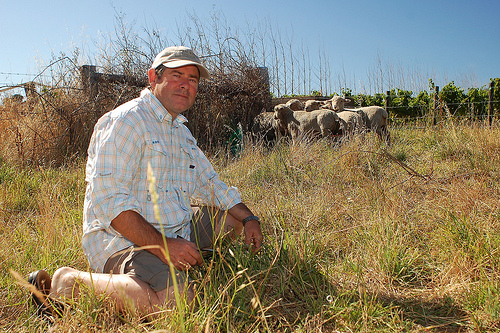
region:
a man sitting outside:
[19, 43, 463, 323]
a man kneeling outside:
[41, 16, 333, 326]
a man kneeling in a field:
[29, 40, 316, 332]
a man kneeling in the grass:
[61, 31, 332, 328]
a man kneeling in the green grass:
[14, 16, 353, 331]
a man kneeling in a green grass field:
[37, 11, 324, 322]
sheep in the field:
[232, 1, 499, 288]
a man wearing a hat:
[26, 38, 303, 320]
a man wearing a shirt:
[25, 34, 301, 319]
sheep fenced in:
[204, 22, 456, 289]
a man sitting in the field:
[18, 30, 303, 327]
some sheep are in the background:
[262, 73, 397, 165]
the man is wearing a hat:
[141, 44, 218, 78]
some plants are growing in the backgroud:
[356, 74, 498, 123]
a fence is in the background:
[2, 60, 88, 105]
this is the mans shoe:
[14, 264, 63, 320]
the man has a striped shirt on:
[117, 119, 199, 228]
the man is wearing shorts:
[101, 192, 241, 294]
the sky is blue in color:
[174, 7, 494, 100]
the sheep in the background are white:
[244, 81, 398, 156]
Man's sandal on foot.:
[28, 272, 58, 319]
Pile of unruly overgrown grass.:
[182, 207, 316, 327]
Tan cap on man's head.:
[147, 43, 212, 78]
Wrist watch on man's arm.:
[244, 216, 264, 224]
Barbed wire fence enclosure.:
[405, 85, 499, 122]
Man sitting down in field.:
[28, 37, 265, 331]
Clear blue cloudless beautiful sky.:
[313, 14, 475, 52]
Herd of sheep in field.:
[251, 92, 386, 148]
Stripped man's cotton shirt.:
[82, 89, 245, 274]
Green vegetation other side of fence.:
[400, 81, 499, 123]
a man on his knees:
[11, 53, 265, 318]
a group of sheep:
[268, 93, 385, 138]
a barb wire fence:
[412, 86, 497, 126]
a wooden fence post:
[433, 87, 437, 123]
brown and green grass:
[338, 164, 463, 281]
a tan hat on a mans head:
[146, 48, 214, 108]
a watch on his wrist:
[236, 210, 265, 229]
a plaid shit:
[82, 111, 240, 262]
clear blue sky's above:
[328, 3, 498, 78]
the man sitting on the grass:
[27, 46, 263, 321]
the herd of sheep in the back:
[250, 95, 390, 146]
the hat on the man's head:
[150, 46, 210, 79]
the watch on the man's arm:
[242, 214, 260, 225]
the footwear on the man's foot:
[26, 268, 75, 319]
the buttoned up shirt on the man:
[80, 88, 242, 273]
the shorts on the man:
[102, 204, 226, 293]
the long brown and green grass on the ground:
[0, 116, 498, 332]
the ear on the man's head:
[145, 67, 157, 89]